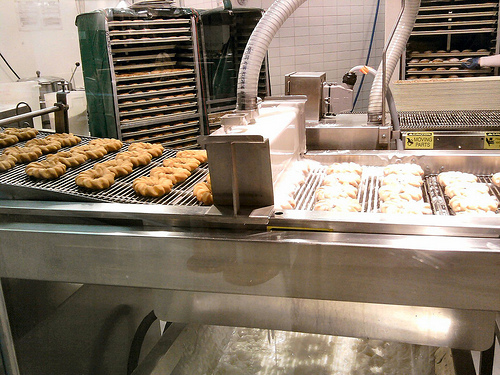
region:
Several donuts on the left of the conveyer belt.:
[0, 126, 216, 202]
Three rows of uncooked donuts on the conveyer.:
[315, 160, 498, 222]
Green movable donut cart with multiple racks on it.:
[72, 9, 212, 154]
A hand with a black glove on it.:
[460, 56, 480, 71]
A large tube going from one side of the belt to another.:
[238, 0, 423, 127]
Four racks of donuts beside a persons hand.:
[406, 48, 493, 82]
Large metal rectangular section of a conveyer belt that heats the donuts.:
[202, 94, 312, 210]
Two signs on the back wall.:
[15, 0, 66, 32]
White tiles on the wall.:
[257, 3, 387, 113]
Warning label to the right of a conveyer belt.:
[405, 128, 435, 153]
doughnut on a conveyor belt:
[133, 176, 173, 198]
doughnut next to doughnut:
[75, 165, 113, 192]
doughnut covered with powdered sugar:
[380, 180, 420, 202]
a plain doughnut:
[117, 150, 147, 168]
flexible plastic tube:
[238, 1, 305, 106]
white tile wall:
[265, 2, 390, 113]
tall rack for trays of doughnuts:
[76, 6, 203, 148]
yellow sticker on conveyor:
[401, 130, 434, 150]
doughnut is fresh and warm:
[117, 150, 149, 165]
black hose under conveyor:
[122, 308, 170, 370]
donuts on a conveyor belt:
[0, 125, 499, 217]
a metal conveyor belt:
[0, 90, 499, 373]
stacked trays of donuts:
[76, 7, 201, 149]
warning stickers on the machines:
[404, 127, 499, 150]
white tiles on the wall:
[261, 0, 376, 112]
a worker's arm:
[463, 53, 499, 69]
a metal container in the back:
[15, 70, 74, 95]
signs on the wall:
[17, 0, 63, 30]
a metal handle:
[68, 60, 79, 81]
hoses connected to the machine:
[235, 0, 421, 123]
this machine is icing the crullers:
[6, 60, 498, 328]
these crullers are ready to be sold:
[309, 152, 499, 226]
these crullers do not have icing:
[9, 125, 200, 199]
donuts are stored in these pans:
[113, 60, 205, 149]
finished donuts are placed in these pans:
[393, 24, 498, 96]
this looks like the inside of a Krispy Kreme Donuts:
[12, 2, 496, 368]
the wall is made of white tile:
[266, 5, 383, 103]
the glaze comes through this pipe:
[223, 0, 312, 195]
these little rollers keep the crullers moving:
[23, 127, 448, 223]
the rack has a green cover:
[75, 3, 215, 162]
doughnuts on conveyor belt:
[105, 135, 184, 195]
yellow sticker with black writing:
[397, 127, 440, 147]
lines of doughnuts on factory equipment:
[301, 155, 477, 223]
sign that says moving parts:
[385, 123, 437, 151]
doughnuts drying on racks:
[132, 88, 184, 128]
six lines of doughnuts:
[0, 122, 227, 208]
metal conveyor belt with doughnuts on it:
[20, 115, 486, 302]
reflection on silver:
[148, 229, 298, 314]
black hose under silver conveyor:
[97, 193, 257, 373]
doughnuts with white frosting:
[402, 44, 486, 88]